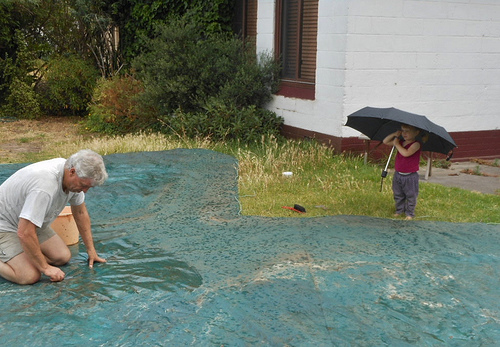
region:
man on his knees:
[4, 133, 101, 286]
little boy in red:
[387, 117, 429, 230]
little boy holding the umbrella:
[347, 98, 449, 227]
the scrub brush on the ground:
[282, 194, 311, 219]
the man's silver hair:
[64, 151, 106, 191]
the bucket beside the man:
[51, 206, 83, 247]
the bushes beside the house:
[128, 27, 268, 147]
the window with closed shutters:
[271, 6, 321, 104]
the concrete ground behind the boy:
[423, 158, 499, 203]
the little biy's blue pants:
[389, 162, 418, 232]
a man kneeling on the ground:
[3, 150, 123, 295]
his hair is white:
[55, 148, 112, 182]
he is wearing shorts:
[0, 214, 71, 259]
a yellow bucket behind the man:
[47, 202, 84, 244]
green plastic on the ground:
[1, 149, 494, 338]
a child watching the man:
[380, 124, 419, 222]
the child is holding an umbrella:
[342, 102, 459, 227]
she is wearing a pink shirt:
[395, 140, 419, 174]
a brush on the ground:
[280, 202, 312, 212]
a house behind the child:
[232, 1, 499, 163]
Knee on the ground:
[10, 274, 38, 284]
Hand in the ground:
[85, 255, 106, 267]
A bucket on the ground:
[63, 218, 73, 238]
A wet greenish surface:
[80, 280, 142, 302]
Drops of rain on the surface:
[220, 234, 260, 257]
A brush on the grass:
[282, 203, 305, 213]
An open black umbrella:
[353, 113, 423, 121]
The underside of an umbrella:
[370, 120, 389, 130]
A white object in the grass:
[280, 170, 292, 177]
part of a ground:
[294, 133, 336, 201]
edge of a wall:
[328, 16, 356, 72]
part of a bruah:
[281, 182, 306, 224]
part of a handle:
[361, 140, 396, 182]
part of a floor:
[461, 159, 475, 179]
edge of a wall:
[323, 53, 343, 93]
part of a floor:
[461, 155, 480, 184]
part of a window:
[287, 46, 305, 78]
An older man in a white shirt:
[0, 146, 107, 284]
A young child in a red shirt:
[379, 123, 420, 218]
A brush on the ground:
[283, 200, 308, 214]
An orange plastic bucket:
[48, 205, 80, 245]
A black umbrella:
[340, 105, 455, 190]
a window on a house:
[277, 0, 317, 85]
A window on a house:
[230, 1, 257, 58]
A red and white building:
[236, 1, 498, 162]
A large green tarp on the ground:
[0, 144, 498, 344]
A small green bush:
[38, 50, 100, 115]